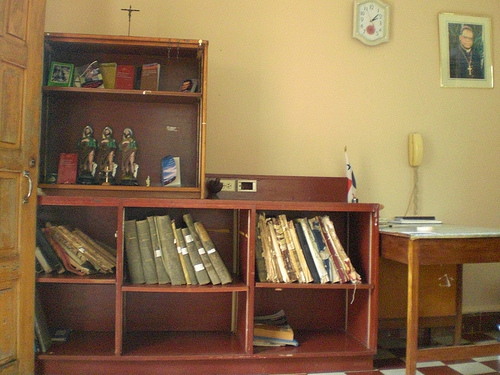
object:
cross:
[121, 3, 141, 38]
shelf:
[39, 32, 209, 199]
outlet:
[218, 177, 238, 194]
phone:
[406, 130, 425, 166]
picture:
[438, 11, 496, 89]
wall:
[44, 1, 499, 318]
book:
[124, 218, 145, 285]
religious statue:
[77, 123, 100, 186]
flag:
[344, 143, 358, 201]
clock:
[351, 1, 391, 47]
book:
[114, 64, 137, 89]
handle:
[22, 169, 35, 205]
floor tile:
[417, 363, 466, 373]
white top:
[412, 225, 439, 235]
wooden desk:
[378, 225, 498, 375]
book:
[137, 64, 160, 89]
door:
[0, 0, 44, 374]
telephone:
[406, 131, 424, 167]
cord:
[404, 167, 419, 218]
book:
[139, 219, 157, 284]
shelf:
[35, 175, 384, 374]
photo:
[446, 21, 485, 79]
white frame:
[352, 0, 392, 48]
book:
[256, 213, 270, 283]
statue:
[97, 126, 120, 187]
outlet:
[236, 180, 257, 191]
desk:
[377, 218, 499, 373]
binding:
[259, 210, 282, 284]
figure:
[118, 126, 140, 187]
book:
[148, 215, 172, 283]